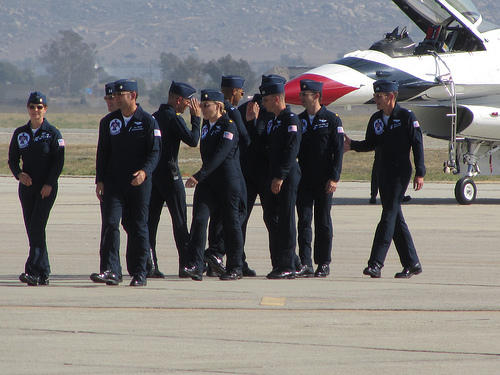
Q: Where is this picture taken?
A: Day time.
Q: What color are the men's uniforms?
A: Blue.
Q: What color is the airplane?
A: White, black and red.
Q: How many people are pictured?
A: 10.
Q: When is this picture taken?
A: While greeting.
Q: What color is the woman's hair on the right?
A: Blonde.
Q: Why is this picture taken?
A: Photography.